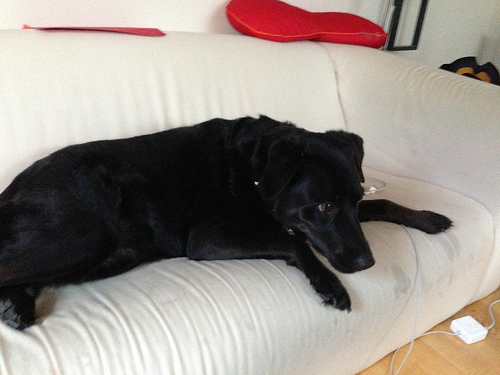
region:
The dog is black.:
[10, 102, 415, 323]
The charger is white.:
[432, 297, 497, 349]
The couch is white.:
[1, 80, 495, 372]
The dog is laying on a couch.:
[5, 102, 401, 293]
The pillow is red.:
[210, 1, 402, 54]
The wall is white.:
[434, 2, 490, 53]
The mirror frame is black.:
[386, 1, 424, 68]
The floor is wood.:
[405, 278, 497, 373]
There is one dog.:
[1, 99, 441, 337]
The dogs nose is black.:
[342, 245, 384, 272]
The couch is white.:
[119, 252, 304, 339]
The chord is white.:
[417, 292, 494, 334]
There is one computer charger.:
[384, 302, 496, 372]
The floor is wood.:
[351, 321, 470, 367]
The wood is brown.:
[408, 344, 465, 369]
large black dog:
[7, 91, 424, 333]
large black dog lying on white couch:
[17, 75, 425, 356]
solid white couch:
[416, 80, 486, 187]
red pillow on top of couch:
[227, 3, 394, 58]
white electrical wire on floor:
[390, 291, 497, 370]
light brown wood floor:
[424, 348, 471, 368]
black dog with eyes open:
[212, 98, 428, 309]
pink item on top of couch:
[19, 12, 170, 54]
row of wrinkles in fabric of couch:
[111, 282, 284, 371]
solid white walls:
[433, 3, 494, 53]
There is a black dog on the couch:
[2, 104, 455, 336]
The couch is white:
[3, 29, 498, 374]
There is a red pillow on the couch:
[227, 6, 406, 49]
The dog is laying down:
[1, 113, 463, 325]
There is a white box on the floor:
[445, 318, 487, 350]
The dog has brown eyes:
[318, 196, 340, 217]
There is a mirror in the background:
[382, 1, 443, 53]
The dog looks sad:
[22, 108, 454, 335]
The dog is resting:
[10, 101, 479, 333]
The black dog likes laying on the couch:
[0, 108, 485, 331]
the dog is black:
[1, 89, 484, 354]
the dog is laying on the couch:
[5, 96, 472, 319]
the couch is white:
[23, 33, 475, 329]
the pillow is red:
[223, 0, 443, 75]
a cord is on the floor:
[397, 301, 494, 348]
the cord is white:
[420, 294, 490, 364]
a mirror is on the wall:
[369, 7, 463, 71]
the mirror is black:
[386, 3, 443, 54]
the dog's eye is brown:
[294, 187, 394, 253]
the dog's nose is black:
[345, 241, 388, 285]